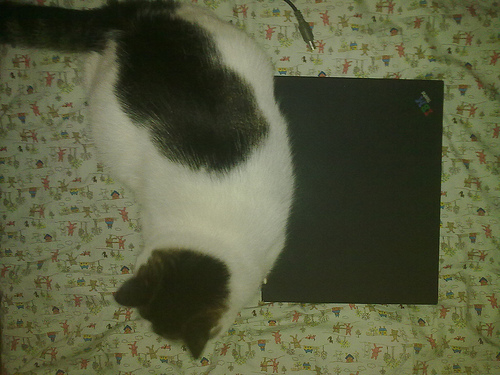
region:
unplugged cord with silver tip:
[276, 7, 325, 57]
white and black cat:
[5, 6, 330, 361]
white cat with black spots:
[12, 20, 342, 371]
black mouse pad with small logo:
[283, 74, 463, 311]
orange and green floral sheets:
[14, 111, 109, 337]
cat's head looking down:
[101, 256, 298, 361]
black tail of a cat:
[3, 3, 107, 58]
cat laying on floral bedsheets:
[10, 10, 377, 372]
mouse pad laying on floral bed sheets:
[273, 50, 465, 339]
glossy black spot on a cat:
[99, 20, 279, 182]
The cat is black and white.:
[94, 62, 294, 340]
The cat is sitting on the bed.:
[30, 19, 300, 335]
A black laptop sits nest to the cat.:
[210, 56, 448, 332]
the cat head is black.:
[115, 245, 225, 355]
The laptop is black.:
[273, 68, 443, 308]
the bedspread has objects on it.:
[15, 177, 120, 362]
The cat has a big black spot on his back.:
[112, 35, 265, 175]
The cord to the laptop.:
[277, 1, 367, 51]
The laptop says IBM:
[406, 77, 432, 137]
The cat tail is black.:
[6, 8, 125, 66]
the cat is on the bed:
[63, 18, 299, 337]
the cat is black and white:
[60, 40, 295, 366]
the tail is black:
[4, 5, 126, 67]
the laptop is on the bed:
[253, 42, 474, 372]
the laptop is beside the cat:
[224, 28, 465, 349]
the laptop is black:
[253, 60, 477, 335]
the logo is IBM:
[407, 82, 444, 121]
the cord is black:
[276, 3, 360, 73]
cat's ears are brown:
[93, 257, 235, 359]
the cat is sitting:
[65, 40, 315, 370]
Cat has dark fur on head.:
[136, 245, 218, 345]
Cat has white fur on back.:
[133, 170, 298, 275]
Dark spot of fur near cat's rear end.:
[124, 51, 293, 205]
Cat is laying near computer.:
[216, 152, 406, 309]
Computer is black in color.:
[390, 68, 463, 160]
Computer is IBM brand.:
[404, 64, 456, 183]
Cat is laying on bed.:
[113, 210, 263, 366]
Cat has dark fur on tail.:
[28, 10, 149, 58]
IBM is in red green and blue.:
[415, 75, 462, 178]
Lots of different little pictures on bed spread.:
[33, 189, 108, 371]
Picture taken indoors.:
[33, 20, 243, 360]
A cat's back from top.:
[94, 27, 289, 367]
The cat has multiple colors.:
[80, 53, 312, 357]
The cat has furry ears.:
[88, 271, 223, 372]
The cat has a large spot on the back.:
[107, 13, 284, 170]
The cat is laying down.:
[70, 60, 301, 374]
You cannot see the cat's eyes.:
[88, 248, 259, 343]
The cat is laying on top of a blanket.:
[45, 118, 492, 323]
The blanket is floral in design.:
[32, 167, 77, 322]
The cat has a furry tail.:
[21, 4, 141, 69]